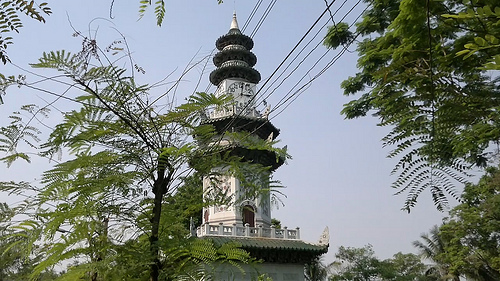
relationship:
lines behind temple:
[271, 27, 328, 91] [208, 21, 295, 243]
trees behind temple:
[422, 51, 476, 93] [208, 21, 295, 243]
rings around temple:
[214, 68, 253, 81] [208, 21, 295, 243]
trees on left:
[422, 51, 476, 93] [1, 80, 83, 95]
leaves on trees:
[25, 6, 48, 14] [422, 51, 476, 93]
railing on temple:
[238, 225, 276, 246] [208, 21, 295, 243]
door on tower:
[228, 201, 262, 227] [215, 37, 255, 67]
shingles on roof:
[225, 237, 272, 243] [269, 237, 324, 255]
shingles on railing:
[225, 237, 272, 243] [238, 225, 276, 246]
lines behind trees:
[271, 27, 328, 91] [422, 51, 476, 93]